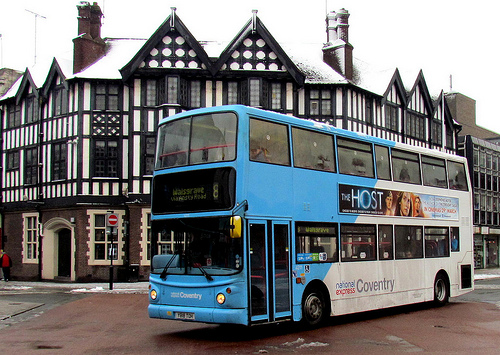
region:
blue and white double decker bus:
[145, 130, 499, 310]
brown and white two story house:
[6, 47, 169, 259]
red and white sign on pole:
[86, 195, 123, 238]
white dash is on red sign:
[102, 211, 117, 223]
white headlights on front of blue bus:
[138, 275, 232, 320]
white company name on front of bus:
[162, 271, 219, 311]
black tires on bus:
[302, 269, 355, 326]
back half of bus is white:
[359, 138, 496, 313]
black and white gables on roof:
[88, 12, 465, 121]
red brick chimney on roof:
[80, 0, 112, 51]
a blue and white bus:
[142, 112, 479, 332]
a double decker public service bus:
[150, 112, 474, 327]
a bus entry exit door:
[240, 217, 289, 322]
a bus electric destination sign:
[161, 180, 221, 201]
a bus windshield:
[149, 220, 239, 278]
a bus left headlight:
[213, 290, 229, 305]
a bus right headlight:
[148, 288, 157, 302]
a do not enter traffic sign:
[103, 210, 118, 228]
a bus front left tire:
[298, 280, 327, 328]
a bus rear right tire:
[433, 270, 450, 305]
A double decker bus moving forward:
[141, 105, 485, 333]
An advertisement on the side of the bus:
[331, 180, 464, 222]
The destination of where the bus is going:
[153, 175, 228, 207]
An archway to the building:
[33, 213, 87, 283]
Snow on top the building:
[86, 23, 136, 90]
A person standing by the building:
[0, 244, 17, 289]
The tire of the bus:
[297, 275, 332, 331]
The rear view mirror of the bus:
[222, 192, 252, 246]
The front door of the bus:
[241, 213, 298, 329]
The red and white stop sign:
[100, 208, 120, 290]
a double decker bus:
[125, 104, 474, 320]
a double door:
[240, 224, 299, 323]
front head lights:
[142, 287, 230, 303]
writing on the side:
[333, 263, 428, 307]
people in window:
[247, 126, 282, 163]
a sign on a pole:
[103, 206, 124, 291]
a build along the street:
[17, 16, 141, 269]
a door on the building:
[43, 212, 77, 282]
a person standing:
[0, 245, 14, 285]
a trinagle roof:
[127, 9, 292, 79]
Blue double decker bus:
[142, 105, 477, 330]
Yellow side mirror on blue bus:
[228, 209, 243, 240]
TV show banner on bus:
[339, 179, 466, 224]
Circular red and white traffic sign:
[107, 210, 119, 228]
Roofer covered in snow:
[0, 36, 443, 111]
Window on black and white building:
[88, 79, 124, 109]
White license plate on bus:
[171, 308, 198, 323]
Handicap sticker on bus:
[302, 260, 310, 275]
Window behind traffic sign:
[90, 213, 120, 263]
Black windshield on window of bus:
[184, 245, 216, 282]